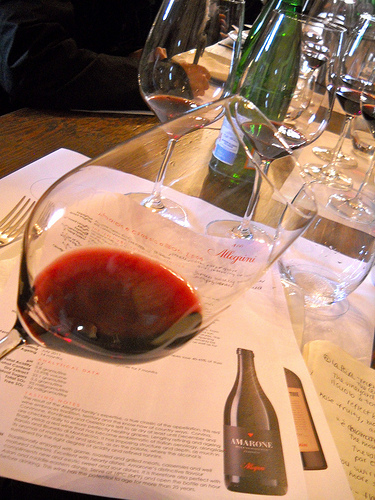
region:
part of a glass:
[177, 56, 209, 93]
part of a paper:
[151, 430, 185, 471]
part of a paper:
[163, 439, 192, 472]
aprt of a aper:
[159, 426, 187, 467]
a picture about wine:
[29, 89, 356, 382]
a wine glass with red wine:
[32, 106, 329, 371]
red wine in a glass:
[40, 111, 301, 363]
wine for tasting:
[21, 156, 271, 353]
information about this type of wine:
[45, 341, 313, 499]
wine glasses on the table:
[151, 5, 232, 134]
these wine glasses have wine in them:
[330, 9, 373, 135]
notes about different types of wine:
[310, 335, 374, 498]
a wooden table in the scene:
[14, 96, 141, 158]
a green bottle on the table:
[224, 3, 304, 184]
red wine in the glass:
[32, 231, 220, 390]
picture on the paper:
[207, 334, 310, 495]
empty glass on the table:
[289, 178, 369, 296]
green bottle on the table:
[213, 3, 299, 195]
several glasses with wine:
[303, 5, 371, 172]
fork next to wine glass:
[2, 188, 47, 254]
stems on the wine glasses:
[132, 123, 309, 262]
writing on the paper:
[24, 347, 222, 478]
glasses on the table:
[91, 84, 372, 279]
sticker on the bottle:
[211, 99, 274, 192]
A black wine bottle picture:
[220, 347, 290, 494]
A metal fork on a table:
[1, 195, 34, 251]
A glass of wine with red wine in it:
[20, 90, 321, 366]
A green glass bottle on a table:
[209, 1, 300, 191]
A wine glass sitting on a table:
[141, 2, 247, 228]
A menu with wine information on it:
[0, 188, 311, 498]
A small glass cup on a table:
[268, 175, 374, 309]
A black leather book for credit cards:
[3, 47, 196, 117]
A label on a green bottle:
[214, 112, 252, 165]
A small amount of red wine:
[21, 242, 206, 364]